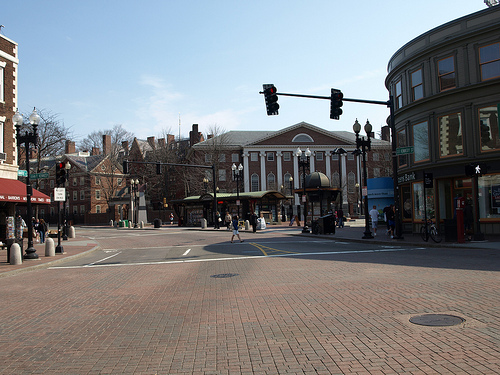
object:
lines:
[47, 247, 427, 270]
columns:
[340, 153, 349, 205]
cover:
[409, 313, 466, 327]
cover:
[210, 273, 239, 279]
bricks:
[239, 354, 251, 362]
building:
[19, 152, 127, 225]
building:
[190, 129, 394, 220]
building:
[112, 134, 188, 225]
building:
[0, 34, 52, 247]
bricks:
[235, 331, 246, 338]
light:
[267, 86, 280, 112]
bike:
[420, 216, 443, 243]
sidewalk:
[287, 225, 500, 249]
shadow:
[201, 226, 500, 272]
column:
[242, 151, 250, 193]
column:
[259, 151, 267, 192]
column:
[276, 151, 284, 193]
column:
[293, 155, 301, 206]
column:
[325, 151, 333, 187]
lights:
[12, 108, 23, 127]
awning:
[0, 176, 51, 205]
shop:
[0, 176, 50, 242]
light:
[332, 92, 344, 117]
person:
[37, 221, 45, 245]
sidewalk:
[0, 230, 98, 272]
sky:
[0, 0, 490, 154]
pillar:
[242, 150, 250, 192]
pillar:
[259, 151, 267, 192]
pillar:
[292, 150, 301, 205]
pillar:
[276, 151, 283, 193]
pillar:
[309, 149, 315, 173]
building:
[240, 120, 394, 224]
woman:
[225, 212, 232, 232]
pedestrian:
[230, 215, 245, 244]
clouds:
[130, 45, 196, 105]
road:
[0, 225, 500, 375]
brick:
[260, 350, 271, 357]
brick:
[188, 336, 197, 343]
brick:
[197, 334, 207, 341]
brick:
[397, 340, 413, 349]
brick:
[300, 306, 313, 316]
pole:
[24, 131, 34, 262]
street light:
[29, 106, 41, 125]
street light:
[12, 107, 24, 127]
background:
[0, 0, 500, 375]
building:
[383, 4, 499, 241]